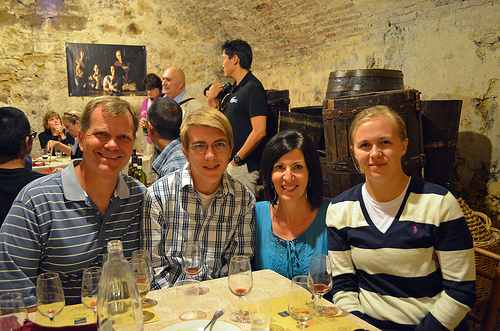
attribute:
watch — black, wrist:
[231, 152, 245, 167]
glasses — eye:
[182, 136, 232, 151]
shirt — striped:
[7, 173, 167, 315]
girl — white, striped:
[323, 104, 478, 329]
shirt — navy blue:
[331, 184, 471, 328]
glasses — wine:
[33, 237, 334, 322]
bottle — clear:
[96, 238, 144, 330]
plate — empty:
[159, 315, 248, 329]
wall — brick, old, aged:
[2, 1, 497, 225]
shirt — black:
[219, 79, 272, 160]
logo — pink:
[410, 219, 422, 234]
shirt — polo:
[7, 165, 190, 292]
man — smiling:
[1, 94, 153, 305]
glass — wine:
[309, 250, 333, 324]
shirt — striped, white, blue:
[19, 171, 140, 246]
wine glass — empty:
[224, 249, 259, 318]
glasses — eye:
[188, 133, 234, 166]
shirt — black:
[218, 69, 268, 173]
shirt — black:
[0, 165, 47, 226]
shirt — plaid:
[136, 165, 260, 292]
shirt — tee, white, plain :
[305, 177, 483, 329]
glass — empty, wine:
[287, 267, 329, 328]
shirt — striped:
[326, 176, 478, 329]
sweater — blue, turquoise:
[251, 190, 336, 290]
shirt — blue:
[253, 197, 328, 274]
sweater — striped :
[328, 180, 478, 328]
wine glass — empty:
[227, 251, 256, 327]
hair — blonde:
[183, 106, 240, 136]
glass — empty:
[223, 250, 336, 317]